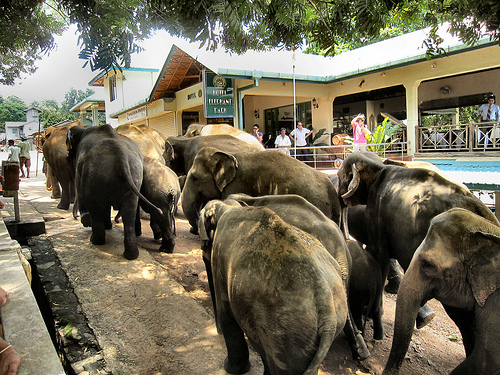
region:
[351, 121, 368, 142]
the man is wearing a pink shirt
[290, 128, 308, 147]
the man is wearing a white shirt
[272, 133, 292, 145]
the man is wearing a white shirt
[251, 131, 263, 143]
the man is wearing a blue shirt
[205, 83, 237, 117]
the sign has a green background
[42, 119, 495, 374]
the elephants are parading by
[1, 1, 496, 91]
tree branches are above the elephants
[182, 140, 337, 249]
the elephant is looking left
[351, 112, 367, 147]
the man has his hand up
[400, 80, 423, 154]
the column is white in color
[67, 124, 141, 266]
This is an elephant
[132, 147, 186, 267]
This is an elephant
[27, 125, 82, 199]
This is an elephant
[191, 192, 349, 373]
This is an elephant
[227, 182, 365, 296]
This is an elephant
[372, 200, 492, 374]
This is an elephant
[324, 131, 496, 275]
This is an elephant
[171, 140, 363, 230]
This is an elephant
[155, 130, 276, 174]
This is an elephant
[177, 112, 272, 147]
This is an elephant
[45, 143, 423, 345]
Group of elephants walking on dirt road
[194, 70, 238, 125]
Green and gold sign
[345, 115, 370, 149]
Person in pink with hand covering face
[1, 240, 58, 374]
Short cement wall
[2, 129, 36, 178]
People walking in front of elephants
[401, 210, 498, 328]
Elephant looking left at people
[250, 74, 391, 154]
People standing at station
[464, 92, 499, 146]
Man in blue shirt and tie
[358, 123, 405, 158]
Large leafy green plant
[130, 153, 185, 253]
Baby elephant walking next to adult elephant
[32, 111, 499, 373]
a group of elephants walking down the street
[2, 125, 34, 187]
two men leading the group of elephants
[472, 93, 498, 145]
a man wearing a neck tie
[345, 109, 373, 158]
a woman in a pink shirt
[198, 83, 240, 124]
a sign that says "Hotel Elephant Pack"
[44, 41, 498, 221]
a hotel next to the street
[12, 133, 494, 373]
a dirt path in between the buildings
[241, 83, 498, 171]
a group of people watching the elephants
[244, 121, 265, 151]
a person talking on the cell phone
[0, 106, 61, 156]
a gray building at the end of the road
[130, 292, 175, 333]
part of a floor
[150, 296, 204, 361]
part of a floor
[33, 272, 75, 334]
part of an edge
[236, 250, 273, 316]
part of a stomach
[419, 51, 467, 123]
part of a balcony